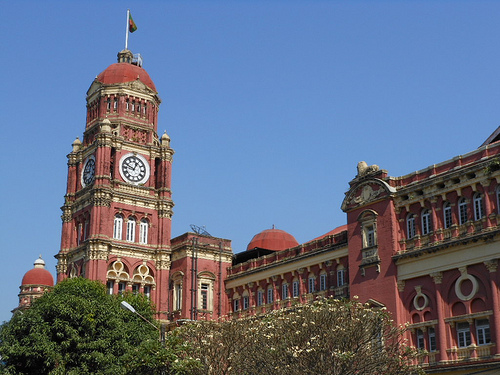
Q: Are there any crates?
A: No, there are no crates.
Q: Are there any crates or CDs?
A: No, there are no crates or cds.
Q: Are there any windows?
A: Yes, there is a window.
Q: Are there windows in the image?
A: Yes, there is a window.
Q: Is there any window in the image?
A: Yes, there is a window.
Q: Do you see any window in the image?
A: Yes, there is a window.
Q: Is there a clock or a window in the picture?
A: Yes, there is a window.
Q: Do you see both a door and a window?
A: No, there is a window but no doors.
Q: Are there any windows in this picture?
A: Yes, there is a window.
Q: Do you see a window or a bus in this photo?
A: Yes, there is a window.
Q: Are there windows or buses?
A: Yes, there is a window.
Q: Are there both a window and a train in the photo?
A: No, there is a window but no trains.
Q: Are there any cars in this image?
A: No, there are no cars.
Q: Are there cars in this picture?
A: No, there are no cars.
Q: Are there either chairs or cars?
A: No, there are no cars or chairs.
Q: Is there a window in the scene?
A: Yes, there is a window.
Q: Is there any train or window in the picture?
A: Yes, there is a window.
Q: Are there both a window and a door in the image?
A: No, there is a window but no doors.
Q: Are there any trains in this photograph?
A: No, there are no trains.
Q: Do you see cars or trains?
A: No, there are no trains or cars.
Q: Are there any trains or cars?
A: No, there are no trains or cars.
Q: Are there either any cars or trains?
A: No, there are no trains or cars.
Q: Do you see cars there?
A: No, there are no cars.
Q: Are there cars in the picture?
A: No, there are no cars.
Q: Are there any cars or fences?
A: No, there are no cars or fences.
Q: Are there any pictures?
A: No, there are no pictures.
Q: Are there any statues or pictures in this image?
A: No, there are no pictures or statues.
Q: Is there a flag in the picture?
A: Yes, there is a flag.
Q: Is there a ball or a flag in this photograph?
A: Yes, there is a flag.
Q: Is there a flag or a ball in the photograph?
A: Yes, there is a flag.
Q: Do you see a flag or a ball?
A: Yes, there is a flag.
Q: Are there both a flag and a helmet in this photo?
A: No, there is a flag but no helmets.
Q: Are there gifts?
A: No, there are no gifts.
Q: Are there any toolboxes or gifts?
A: No, there are no gifts or toolboxes.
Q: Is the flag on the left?
A: Yes, the flag is on the left of the image.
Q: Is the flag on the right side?
A: No, the flag is on the left of the image.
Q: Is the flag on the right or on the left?
A: The flag is on the left of the image.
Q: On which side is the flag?
A: The flag is on the left of the image.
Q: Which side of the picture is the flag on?
A: The flag is on the left of the image.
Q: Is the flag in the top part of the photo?
A: Yes, the flag is in the top of the image.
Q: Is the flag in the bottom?
A: No, the flag is in the top of the image.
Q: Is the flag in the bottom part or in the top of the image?
A: The flag is in the top of the image.